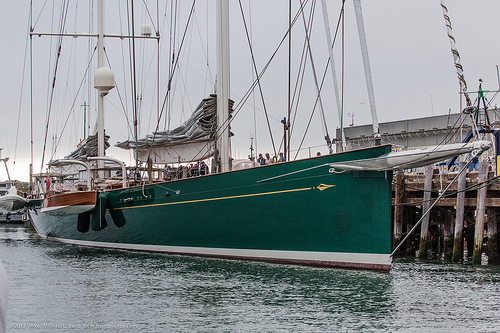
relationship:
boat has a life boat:
[15, 4, 418, 284] [32, 180, 92, 216]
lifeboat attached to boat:
[35, 188, 102, 218] [26, 0, 494, 275]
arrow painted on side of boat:
[102, 177, 338, 216] [22, 136, 496, 276]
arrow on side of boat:
[105, 182, 337, 211] [22, 136, 496, 276]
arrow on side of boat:
[102, 177, 338, 216] [22, 136, 496, 276]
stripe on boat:
[100, 180, 336, 213] [22, 136, 496, 276]